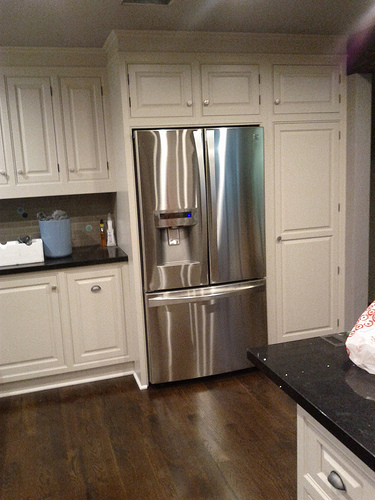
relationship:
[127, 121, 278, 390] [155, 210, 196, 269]
fridge has dispenser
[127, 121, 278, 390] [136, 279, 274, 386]
fridge has freezer